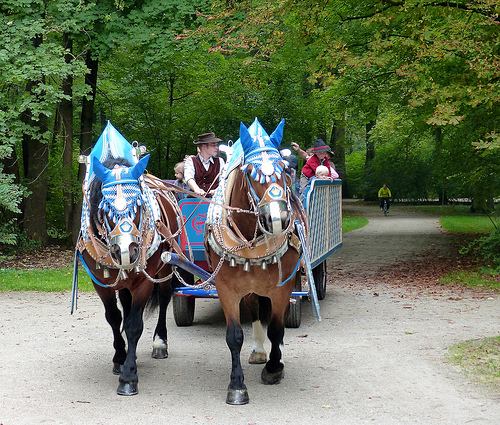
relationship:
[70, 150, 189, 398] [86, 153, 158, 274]
horse has head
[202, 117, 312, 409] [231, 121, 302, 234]
horse has head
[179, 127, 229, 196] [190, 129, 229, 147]
man has head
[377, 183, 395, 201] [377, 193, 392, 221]
man riding bike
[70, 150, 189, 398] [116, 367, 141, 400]
horse has hoof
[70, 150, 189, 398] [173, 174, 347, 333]
horse pulling wagon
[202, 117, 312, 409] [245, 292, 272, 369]
horse has leg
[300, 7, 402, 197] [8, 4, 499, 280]
tree in background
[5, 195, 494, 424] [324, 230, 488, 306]
path covered with leaves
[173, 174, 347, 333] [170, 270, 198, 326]
wagon has wheel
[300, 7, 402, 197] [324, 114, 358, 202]
tree has trunk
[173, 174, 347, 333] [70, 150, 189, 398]
wagon led by horse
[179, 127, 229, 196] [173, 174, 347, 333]
man driving wagon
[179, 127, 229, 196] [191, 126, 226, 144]
man has hat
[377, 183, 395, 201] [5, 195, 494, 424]
man on path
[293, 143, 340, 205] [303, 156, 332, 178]
child swearing sweater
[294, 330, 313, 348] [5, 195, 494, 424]
spot on path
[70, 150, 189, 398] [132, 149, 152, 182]
horse has ear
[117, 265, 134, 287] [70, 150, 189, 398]
bell in front of horse